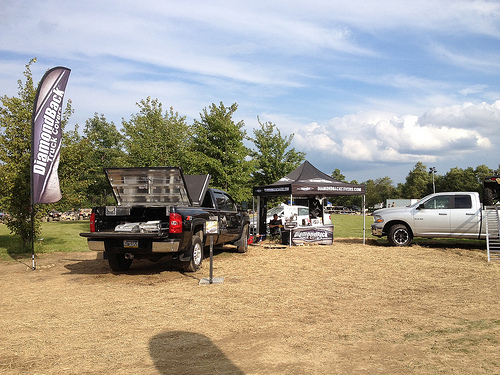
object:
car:
[370, 192, 500, 247]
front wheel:
[237, 228, 248, 253]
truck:
[78, 165, 250, 275]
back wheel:
[179, 234, 204, 272]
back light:
[169, 213, 182, 234]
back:
[78, 166, 193, 274]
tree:
[0, 57, 75, 255]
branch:
[61, 98, 75, 129]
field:
[0, 215, 500, 375]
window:
[453, 195, 472, 209]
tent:
[250, 160, 367, 250]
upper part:
[252, 160, 366, 197]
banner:
[30, 65, 72, 270]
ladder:
[484, 205, 500, 264]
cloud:
[413, 100, 500, 145]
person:
[269, 214, 293, 246]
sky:
[1, 1, 500, 186]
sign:
[198, 219, 226, 284]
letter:
[33, 164, 45, 176]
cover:
[102, 166, 193, 207]